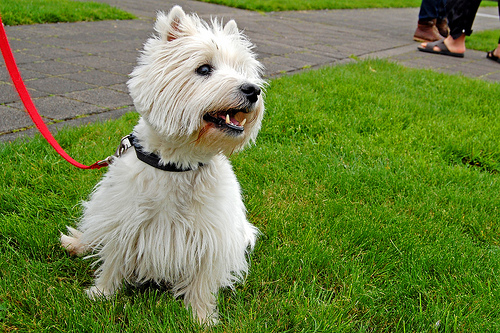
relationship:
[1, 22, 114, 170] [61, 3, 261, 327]
leash for dog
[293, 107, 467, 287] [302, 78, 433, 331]
grass on ground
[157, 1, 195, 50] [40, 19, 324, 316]
ear on dog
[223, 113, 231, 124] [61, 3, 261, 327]
teeth on dog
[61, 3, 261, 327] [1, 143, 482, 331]
dog sitting in grass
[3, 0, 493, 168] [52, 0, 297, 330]
sidewalk behind dog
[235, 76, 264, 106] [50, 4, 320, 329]
nose of dog